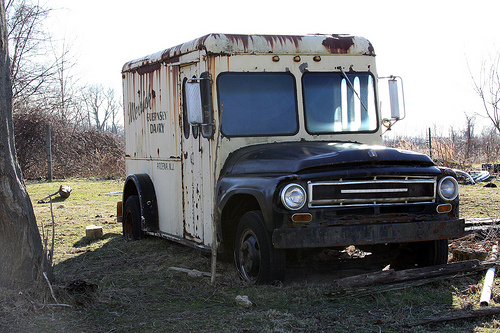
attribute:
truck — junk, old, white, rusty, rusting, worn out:
[118, 31, 465, 285]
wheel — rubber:
[124, 197, 141, 242]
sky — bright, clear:
[1, 1, 500, 142]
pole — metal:
[47, 123, 54, 184]